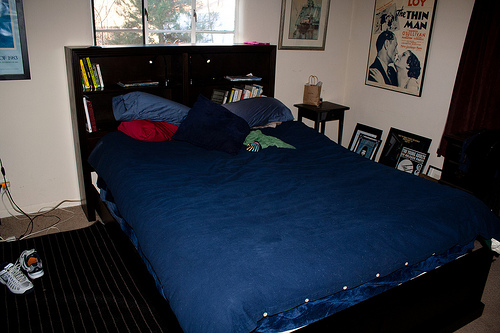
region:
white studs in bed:
[254, 299, 313, 331]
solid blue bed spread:
[169, 150, 404, 294]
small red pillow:
[120, 108, 188, 149]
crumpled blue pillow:
[105, 87, 195, 130]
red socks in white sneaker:
[19, 242, 56, 289]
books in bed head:
[70, 49, 205, 93]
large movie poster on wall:
[362, 5, 447, 130]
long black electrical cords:
[10, 186, 98, 246]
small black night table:
[295, 93, 350, 134]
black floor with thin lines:
[70, 275, 161, 320]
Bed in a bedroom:
[54, 31, 498, 331]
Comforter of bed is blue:
[80, 111, 498, 331]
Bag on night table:
[293, 66, 330, 111]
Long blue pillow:
[104, 87, 295, 137]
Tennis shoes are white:
[1, 236, 56, 302]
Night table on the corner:
[291, 96, 348, 147]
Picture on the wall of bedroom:
[268, 0, 336, 62]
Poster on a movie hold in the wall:
[356, 0, 445, 105]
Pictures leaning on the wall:
[344, 116, 441, 176]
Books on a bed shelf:
[68, 54, 111, 94]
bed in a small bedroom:
[36, 10, 483, 317]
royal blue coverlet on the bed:
[105, 163, 479, 326]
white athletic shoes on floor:
[0, 235, 45, 300]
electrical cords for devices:
[0, 162, 81, 247]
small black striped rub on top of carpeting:
[55, 237, 136, 317]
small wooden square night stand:
[292, 98, 343, 126]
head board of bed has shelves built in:
[56, 30, 276, 101]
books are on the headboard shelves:
[75, 47, 116, 127]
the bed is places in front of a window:
[85, 0, 240, 61]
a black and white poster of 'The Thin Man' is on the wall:
[334, 4, 431, 106]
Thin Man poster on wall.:
[357, 2, 438, 105]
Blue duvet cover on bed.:
[78, 112, 499, 329]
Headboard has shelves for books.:
[67, 32, 301, 226]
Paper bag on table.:
[295, 72, 330, 109]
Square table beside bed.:
[291, 87, 348, 150]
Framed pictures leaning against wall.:
[347, 118, 448, 186]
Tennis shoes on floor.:
[0, 245, 47, 296]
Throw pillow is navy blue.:
[169, 95, 255, 156]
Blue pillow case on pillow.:
[112, 87, 192, 128]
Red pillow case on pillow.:
[115, 117, 184, 147]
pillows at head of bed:
[111, 87, 288, 142]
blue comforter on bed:
[117, 134, 460, 317]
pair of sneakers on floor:
[4, 236, 54, 299]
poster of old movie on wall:
[356, 3, 439, 107]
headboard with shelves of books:
[62, 34, 282, 117]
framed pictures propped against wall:
[346, 110, 445, 185]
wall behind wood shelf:
[75, 4, 247, 60]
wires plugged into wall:
[13, 160, 64, 240]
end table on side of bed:
[294, 87, 356, 145]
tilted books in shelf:
[74, 56, 111, 94]